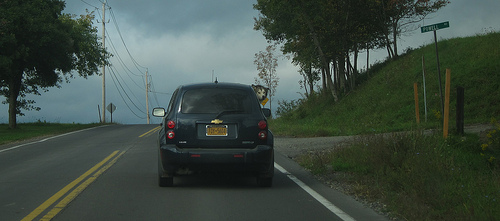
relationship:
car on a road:
[152, 77, 272, 186] [78, 132, 143, 200]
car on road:
[153, 79, 282, 189] [9, 122, 328, 213]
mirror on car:
[147, 103, 172, 117] [153, 79, 282, 189]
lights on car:
[163, 114, 276, 147] [159, 75, 279, 185]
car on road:
[152, 77, 272, 186] [0, 131, 314, 220]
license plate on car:
[208, 128, 227, 135] [153, 79, 282, 189]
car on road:
[152, 77, 272, 186] [2, 123, 390, 220]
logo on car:
[208, 114, 226, 129] [152, 77, 272, 186]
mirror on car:
[152, 107, 166, 117] [153, 79, 282, 189]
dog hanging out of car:
[251, 82, 272, 104] [152, 77, 272, 186]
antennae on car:
[209, 74, 222, 84] [152, 77, 272, 186]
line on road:
[19, 146, 127, 219] [2, 123, 390, 220]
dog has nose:
[251, 84, 269, 100] [262, 95, 263, 97]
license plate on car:
[202, 119, 230, 140] [152, 77, 272, 186]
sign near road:
[104, 100, 118, 123] [6, 112, 358, 219]